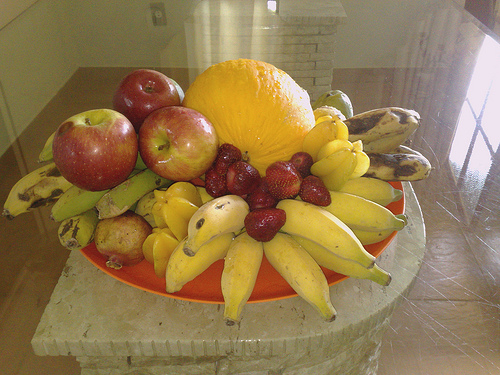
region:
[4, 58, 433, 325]
the fruit on a platter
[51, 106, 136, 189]
the apple on the pile of fruit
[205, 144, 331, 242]
the pile of strawberries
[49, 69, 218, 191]
the group of apples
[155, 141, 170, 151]
the stem of the apple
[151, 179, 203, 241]
the starfruit in the pile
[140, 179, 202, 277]
the two starfruit in the pile of fruit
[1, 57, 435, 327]
the bananas in the pile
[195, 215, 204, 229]
the brown spot on the banana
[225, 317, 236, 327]
the end of the banana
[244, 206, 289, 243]
juicy looking strawberry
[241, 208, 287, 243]
strawberry on top of bananas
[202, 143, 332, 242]
group of strawberries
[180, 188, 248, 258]
yellow banana with black marks on it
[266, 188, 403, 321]
five yellow bananas on an orange plate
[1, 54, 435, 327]
large orange plate of fruits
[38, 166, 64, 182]
black marks on a banana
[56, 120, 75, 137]
brown spot on an apple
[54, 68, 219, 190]
three red juicy looking apples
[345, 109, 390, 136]
large black mark on a yellow fruit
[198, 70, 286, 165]
large orange inthe bowl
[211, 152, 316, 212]
strawberries are red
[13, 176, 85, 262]
bananas have markings on them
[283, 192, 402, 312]
bananas are fresh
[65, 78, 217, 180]
three apples in the bowl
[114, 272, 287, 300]
dish is orange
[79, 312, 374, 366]
fruit is on a table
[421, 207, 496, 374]
floor is white tiled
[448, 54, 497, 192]
sunlight coming thru window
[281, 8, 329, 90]
part of wall made of white brick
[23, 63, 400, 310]
fruit arranged on a platter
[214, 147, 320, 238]
strawberries with the stems removed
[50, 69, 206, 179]
apples on a fruit arrangement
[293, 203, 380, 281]
bananas in a fruit arrangement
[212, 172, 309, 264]
strawberries and bananas on a fruit platter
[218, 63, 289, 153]
large yellow fruit on a platter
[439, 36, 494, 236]
reflection of a window in the glass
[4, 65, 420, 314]
fruits arranged on an orange platter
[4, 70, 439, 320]
large fruit plate on a glass table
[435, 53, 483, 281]
shiny glass table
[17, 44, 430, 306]
Lot of fruits kept in the orange color plate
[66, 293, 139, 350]
White color stone table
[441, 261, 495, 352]
Brown color floor tiles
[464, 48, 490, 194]
Glass windows in the building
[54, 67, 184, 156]
Three apple kept in the plate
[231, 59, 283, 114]
Orange kept in the plate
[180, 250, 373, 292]
Bananas kept in the plate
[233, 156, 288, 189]
Strawberry kept in the plate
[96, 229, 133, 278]
Pomegranate kept in the plate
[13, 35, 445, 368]
Orange color plate with fruits kept in the table